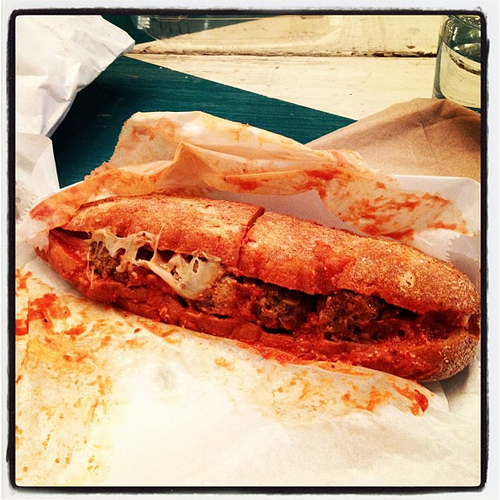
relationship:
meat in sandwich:
[236, 276, 410, 340] [38, 200, 471, 360]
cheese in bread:
[96, 232, 225, 302] [35, 192, 480, 386]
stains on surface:
[32, 283, 132, 452] [5, 304, 93, 488]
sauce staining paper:
[366, 199, 392, 218] [109, 95, 474, 280]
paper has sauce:
[11, 356, 425, 483] [18, 310, 82, 409]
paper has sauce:
[25, 308, 215, 498] [25, 315, 400, 423]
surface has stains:
[221, 19, 389, 112] [348, 43, 433, 65]